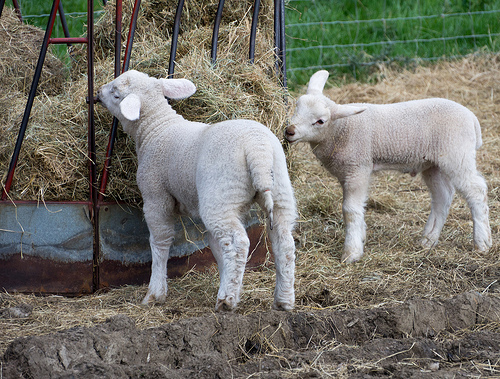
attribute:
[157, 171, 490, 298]
legs — white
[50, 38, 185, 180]
food — hay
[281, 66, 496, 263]
sheep — white, eating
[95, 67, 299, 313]
sheep — white, eating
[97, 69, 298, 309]
baby lamb — away-faced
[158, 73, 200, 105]
lamb ear — white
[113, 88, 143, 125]
lamb ear — white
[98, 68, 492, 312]
lambs — white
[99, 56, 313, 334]
lamb — white, wooly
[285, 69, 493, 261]
lamb — wooly, eating, baby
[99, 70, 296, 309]
lamb — eating, baby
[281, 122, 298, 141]
sheep's nose — brown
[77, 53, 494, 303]
lambs — babies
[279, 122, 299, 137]
nose — brown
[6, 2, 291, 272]
feeder — blue, red 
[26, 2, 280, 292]
feeder — metal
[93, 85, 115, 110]
nose — brown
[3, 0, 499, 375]
picture — outdoors